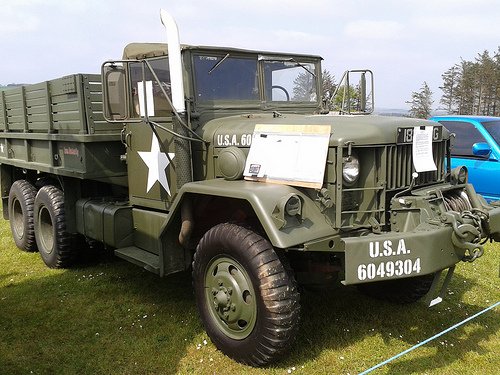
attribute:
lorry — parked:
[14, 51, 475, 307]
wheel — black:
[263, 79, 293, 102]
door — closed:
[126, 120, 192, 215]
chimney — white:
[157, 14, 190, 121]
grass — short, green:
[4, 269, 169, 374]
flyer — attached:
[245, 122, 332, 196]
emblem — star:
[136, 134, 182, 197]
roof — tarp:
[132, 32, 204, 60]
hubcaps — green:
[206, 255, 260, 342]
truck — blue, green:
[439, 116, 500, 184]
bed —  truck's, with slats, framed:
[8, 87, 113, 138]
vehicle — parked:
[16, 77, 372, 190]